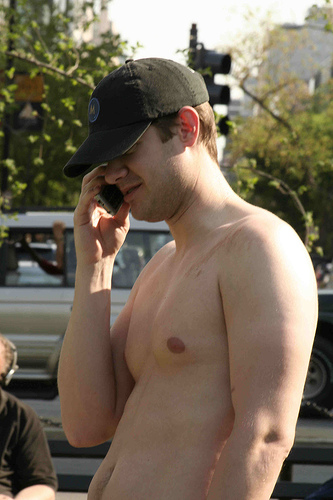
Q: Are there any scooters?
A: No, there are no scooters.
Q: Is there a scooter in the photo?
A: No, there are no scooters.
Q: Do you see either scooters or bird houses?
A: No, there are no scooters or bird houses.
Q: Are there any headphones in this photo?
A: Yes, there are headphones.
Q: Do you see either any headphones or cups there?
A: Yes, there are headphones.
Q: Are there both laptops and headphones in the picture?
A: No, there are headphones but no laptops.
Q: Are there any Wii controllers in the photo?
A: No, there are no Wii controllers.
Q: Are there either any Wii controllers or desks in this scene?
A: No, there are no Wii controllers or desks.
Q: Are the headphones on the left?
A: Yes, the headphones are on the left of the image.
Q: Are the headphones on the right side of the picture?
A: No, the headphones are on the left of the image.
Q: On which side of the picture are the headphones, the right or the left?
A: The headphones are on the left of the image.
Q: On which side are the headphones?
A: The headphones are on the left of the image.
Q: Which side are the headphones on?
A: The headphones are on the left of the image.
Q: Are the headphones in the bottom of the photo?
A: Yes, the headphones are in the bottom of the image.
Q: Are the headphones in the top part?
A: No, the headphones are in the bottom of the image.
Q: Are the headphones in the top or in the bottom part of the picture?
A: The headphones are in the bottom of the image.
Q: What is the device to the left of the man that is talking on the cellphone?
A: The device is headphones.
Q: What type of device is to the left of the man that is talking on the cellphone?
A: The device is headphones.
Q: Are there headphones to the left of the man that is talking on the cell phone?
A: Yes, there are headphones to the left of the man.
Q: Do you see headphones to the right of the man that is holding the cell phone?
A: No, the headphones are to the left of the man.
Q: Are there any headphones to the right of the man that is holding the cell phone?
A: No, the headphones are to the left of the man.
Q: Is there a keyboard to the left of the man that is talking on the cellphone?
A: No, there are headphones to the left of the man.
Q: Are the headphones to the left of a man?
A: Yes, the headphones are to the left of a man.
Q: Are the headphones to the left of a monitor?
A: No, the headphones are to the left of a man.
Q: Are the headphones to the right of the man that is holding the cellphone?
A: No, the headphones are to the left of the man.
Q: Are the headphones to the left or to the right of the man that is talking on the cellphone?
A: The headphones are to the left of the man.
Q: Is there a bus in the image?
A: No, there are no buses.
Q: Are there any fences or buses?
A: No, there are no buses or fences.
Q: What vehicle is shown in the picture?
A: The vehicle is a car.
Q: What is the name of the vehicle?
A: The vehicle is a car.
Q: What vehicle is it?
A: The vehicle is a car.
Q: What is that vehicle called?
A: That is a car.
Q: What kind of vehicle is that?
A: That is a car.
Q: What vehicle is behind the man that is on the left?
A: The vehicle is a car.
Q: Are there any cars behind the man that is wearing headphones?
A: Yes, there is a car behind the man.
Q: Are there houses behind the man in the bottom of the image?
A: No, there is a car behind the man.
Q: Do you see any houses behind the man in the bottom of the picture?
A: No, there is a car behind the man.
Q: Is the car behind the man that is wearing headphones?
A: Yes, the car is behind the man.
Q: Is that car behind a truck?
A: No, the car is behind the man.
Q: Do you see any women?
A: No, there are no women.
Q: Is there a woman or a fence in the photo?
A: No, there are no women or fences.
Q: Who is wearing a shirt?
A: The man is wearing a shirt.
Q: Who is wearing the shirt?
A: The man is wearing a shirt.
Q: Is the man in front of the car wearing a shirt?
A: Yes, the man is wearing a shirt.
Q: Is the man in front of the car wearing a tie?
A: No, the man is wearing a shirt.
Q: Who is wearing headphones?
A: The man is wearing headphones.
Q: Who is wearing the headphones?
A: The man is wearing headphones.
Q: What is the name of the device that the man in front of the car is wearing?
A: The device is headphones.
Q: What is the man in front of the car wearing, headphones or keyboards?
A: The man is wearing headphones.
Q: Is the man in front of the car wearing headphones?
A: Yes, the man is wearing headphones.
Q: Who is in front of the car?
A: The man is in front of the car.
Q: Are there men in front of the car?
A: Yes, there is a man in front of the car.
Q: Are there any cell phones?
A: Yes, there is a cell phone.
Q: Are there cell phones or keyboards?
A: Yes, there is a cell phone.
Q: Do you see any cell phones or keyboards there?
A: Yes, there is a cell phone.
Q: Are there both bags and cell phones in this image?
A: No, there is a cell phone but no bags.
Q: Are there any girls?
A: No, there are no girls.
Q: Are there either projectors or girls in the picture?
A: No, there are no girls or projectors.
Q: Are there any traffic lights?
A: Yes, there is a traffic light.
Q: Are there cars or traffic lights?
A: Yes, there is a traffic light.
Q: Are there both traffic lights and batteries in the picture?
A: No, there is a traffic light but no batteries.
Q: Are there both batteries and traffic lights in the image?
A: No, there is a traffic light but no batteries.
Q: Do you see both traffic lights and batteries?
A: No, there is a traffic light but no batteries.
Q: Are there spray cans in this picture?
A: No, there are no spray cans.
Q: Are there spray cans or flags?
A: No, there are no spray cans or flags.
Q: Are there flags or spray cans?
A: No, there are no spray cans or flags.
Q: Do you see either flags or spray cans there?
A: No, there are no spray cans or flags.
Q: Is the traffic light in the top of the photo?
A: Yes, the traffic light is in the top of the image.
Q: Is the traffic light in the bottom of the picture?
A: No, the traffic light is in the top of the image.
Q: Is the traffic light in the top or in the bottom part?
A: The traffic light is in the top of the image.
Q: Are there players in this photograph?
A: No, there are no players.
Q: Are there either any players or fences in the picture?
A: No, there are no players or fences.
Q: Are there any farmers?
A: No, there are no farmers.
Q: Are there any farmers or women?
A: No, there are no farmers or women.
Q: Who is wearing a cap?
A: The man is wearing a cap.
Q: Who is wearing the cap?
A: The man is wearing a cap.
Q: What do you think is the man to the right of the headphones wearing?
A: The man is wearing a cap.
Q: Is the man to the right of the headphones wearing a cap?
A: Yes, the man is wearing a cap.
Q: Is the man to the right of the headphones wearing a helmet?
A: No, the man is wearing a cap.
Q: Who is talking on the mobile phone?
A: The man is talking on the mobile phone.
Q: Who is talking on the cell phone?
A: The man is talking on the mobile phone.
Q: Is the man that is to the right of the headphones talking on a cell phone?
A: Yes, the man is talking on a cell phone.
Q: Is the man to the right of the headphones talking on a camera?
A: No, the man is talking on a cell phone.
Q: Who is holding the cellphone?
A: The man is holding the cellphone.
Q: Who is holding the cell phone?
A: The man is holding the cellphone.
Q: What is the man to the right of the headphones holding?
A: The man is holding the cellphone.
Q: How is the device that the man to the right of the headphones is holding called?
A: The device is a cell phone.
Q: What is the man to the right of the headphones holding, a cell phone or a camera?
A: The man is holding a cell phone.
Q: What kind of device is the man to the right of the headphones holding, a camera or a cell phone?
A: The man is holding a cell phone.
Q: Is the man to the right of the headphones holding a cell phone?
A: Yes, the man is holding a cell phone.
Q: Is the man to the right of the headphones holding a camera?
A: No, the man is holding a cell phone.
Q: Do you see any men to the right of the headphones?
A: Yes, there is a man to the right of the headphones.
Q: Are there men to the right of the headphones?
A: Yes, there is a man to the right of the headphones.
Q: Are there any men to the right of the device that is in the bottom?
A: Yes, there is a man to the right of the headphones.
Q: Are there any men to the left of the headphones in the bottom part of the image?
A: No, the man is to the right of the headphones.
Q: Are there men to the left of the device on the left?
A: No, the man is to the right of the headphones.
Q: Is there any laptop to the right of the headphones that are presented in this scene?
A: No, there is a man to the right of the headphones.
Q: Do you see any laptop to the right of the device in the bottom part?
A: No, there is a man to the right of the headphones.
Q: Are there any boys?
A: No, there are no boys.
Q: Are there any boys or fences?
A: No, there are no boys or fences.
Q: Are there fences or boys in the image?
A: No, there are no boys or fences.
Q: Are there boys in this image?
A: No, there are no boys.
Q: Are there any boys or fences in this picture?
A: No, there are no boys or fences.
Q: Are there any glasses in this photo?
A: No, there are no glasses.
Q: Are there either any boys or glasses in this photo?
A: No, there are no glasses or boys.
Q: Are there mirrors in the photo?
A: No, there are no mirrors.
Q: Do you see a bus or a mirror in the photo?
A: No, there are no mirrors or buses.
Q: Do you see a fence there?
A: No, there are no fences.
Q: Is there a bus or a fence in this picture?
A: No, there are no fences or buses.